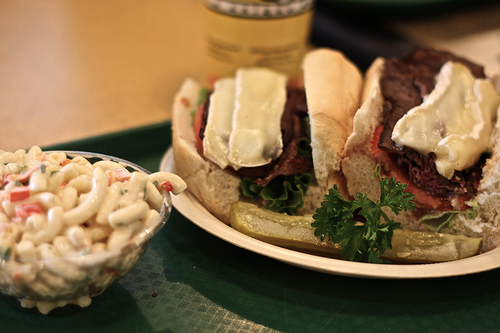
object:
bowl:
[0, 146, 175, 316]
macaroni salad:
[0, 144, 190, 316]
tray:
[0, 117, 499, 333]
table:
[1, 0, 321, 157]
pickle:
[228, 196, 486, 267]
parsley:
[308, 162, 418, 267]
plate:
[155, 142, 500, 284]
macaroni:
[143, 169, 190, 196]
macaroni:
[104, 195, 153, 230]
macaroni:
[29, 161, 67, 195]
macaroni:
[20, 204, 67, 248]